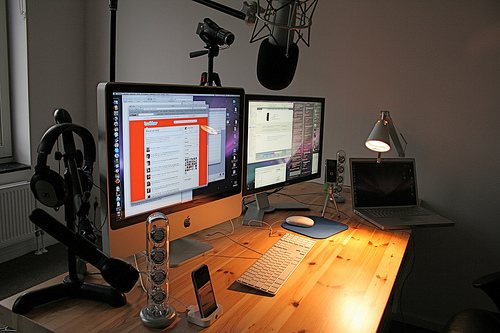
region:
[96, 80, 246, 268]
an Apple iMac computer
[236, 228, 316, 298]
a wired Apple USB keyboard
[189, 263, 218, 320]
a black Apple iPhone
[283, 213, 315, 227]
a wired Apple Mighty Mouse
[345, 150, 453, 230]
an Apple MacBook computer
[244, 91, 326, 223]
a black computer monitor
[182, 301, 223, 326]
a white Apple dock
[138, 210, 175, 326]
a clear desktop speaker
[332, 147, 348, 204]
a clear desktop speaker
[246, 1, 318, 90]
a professional microphone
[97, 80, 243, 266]
A large, silver, Apple-branded monitor displaying twitter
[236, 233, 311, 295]
A white Mac keyboard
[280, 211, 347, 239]
A white mouse on a plain blue mousepad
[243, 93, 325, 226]
A large black monitor next to the silver monitor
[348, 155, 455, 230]
An open, silver laptop hanging off the desk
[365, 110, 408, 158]
A metal desk lamp, turned on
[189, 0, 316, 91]
A professional microphone hanging down over the desk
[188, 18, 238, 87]
A camera aimed over the monitors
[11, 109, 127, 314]
A black stand with assorted audio equipment hanging on it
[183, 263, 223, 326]
An iPhone or iPod on a white charging dock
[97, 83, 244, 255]
a silver monitor on a desk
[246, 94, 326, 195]
a black monitor on a desk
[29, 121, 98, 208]
black headphones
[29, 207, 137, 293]
a black mile propped on a stand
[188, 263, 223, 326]
a cell phone on a white charger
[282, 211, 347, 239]
a white mouse on a blue mouse pad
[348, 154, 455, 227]
a silvery laptop on a desk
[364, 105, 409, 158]
a silvery desk lamp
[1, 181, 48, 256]
a white radiator against the wall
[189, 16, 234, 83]
a video camera on a tripod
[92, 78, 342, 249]
two computer monitors sitting next to each other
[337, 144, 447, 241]
laptop on the desk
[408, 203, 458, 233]
corner of the laptop hanging off the desk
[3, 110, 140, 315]
headphones and a microphone on a stand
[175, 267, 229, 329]
touch screen electronic device in a charging block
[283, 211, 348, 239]
mouse on the mouse pad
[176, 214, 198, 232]
small Apple logo on the monitor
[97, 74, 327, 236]
both monitors are on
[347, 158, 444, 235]
laptop is off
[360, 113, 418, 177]
lamp hanging over the laptop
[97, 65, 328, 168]
Two desktop computer kept in the wooden table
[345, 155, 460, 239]
A laptop kept in the wooden table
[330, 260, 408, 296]
Brown color wooden table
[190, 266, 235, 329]
Mobile phone with charger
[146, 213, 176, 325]
Speakers of the computer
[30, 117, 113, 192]
Blackcolor headphone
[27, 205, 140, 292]
Black color mic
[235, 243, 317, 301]
White color keyboard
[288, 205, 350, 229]
White color mouse with blue color mouse pad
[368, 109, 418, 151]
Night lamp near the laptop